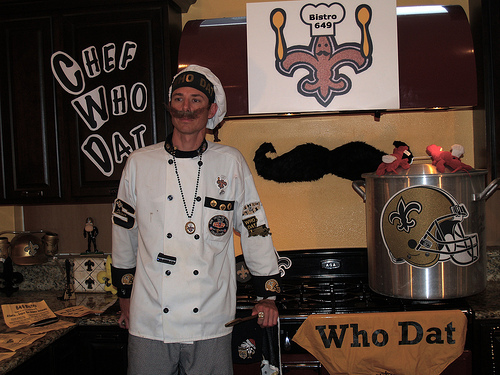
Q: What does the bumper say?
A: Who Dat.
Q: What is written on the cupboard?
A: Chef Who Dat.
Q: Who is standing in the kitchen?
A: A chef.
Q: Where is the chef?
A: In the kitchen.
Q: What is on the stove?
A: A pot.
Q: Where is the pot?
A: On the stove.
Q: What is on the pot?
A: A helmet sticker.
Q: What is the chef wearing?
A: A white shirt.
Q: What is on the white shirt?
A: Buttons.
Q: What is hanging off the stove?
A: A towel.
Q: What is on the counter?
A: Papers.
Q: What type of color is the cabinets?
A: Black.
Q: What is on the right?
A: Huge pot.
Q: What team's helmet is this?
A: New Orleans Saints.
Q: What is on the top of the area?
A: A restaurant's logo.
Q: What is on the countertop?
A: Papers.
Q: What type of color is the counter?
A: Brown.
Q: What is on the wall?
A: Black mustache.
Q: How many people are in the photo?
A: One.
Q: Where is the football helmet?
A: On the pot.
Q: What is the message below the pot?
A: Who dat.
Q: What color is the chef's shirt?
A: White.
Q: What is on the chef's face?
A: A mustache.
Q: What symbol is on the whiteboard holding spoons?
A: Fleur de lis.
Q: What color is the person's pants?
A: Gray.